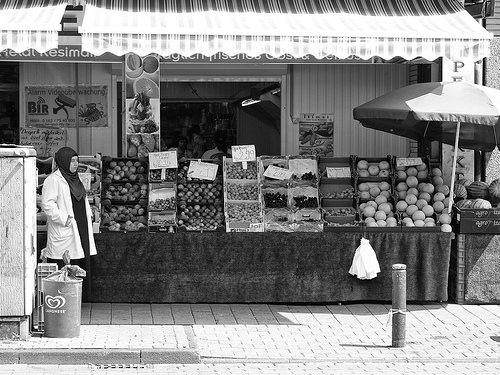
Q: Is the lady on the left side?
A: Yes, the lady is on the left of the image.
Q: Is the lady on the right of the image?
A: No, the lady is on the left of the image.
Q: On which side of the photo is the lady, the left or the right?
A: The lady is on the left of the image.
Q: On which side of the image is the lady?
A: The lady is on the left of the image.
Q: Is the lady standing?
A: Yes, the lady is standing.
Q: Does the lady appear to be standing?
A: Yes, the lady is standing.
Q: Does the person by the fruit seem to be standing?
A: Yes, the lady is standing.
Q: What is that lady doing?
A: The lady is standing.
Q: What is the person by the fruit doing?
A: The lady is standing.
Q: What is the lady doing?
A: The lady is standing.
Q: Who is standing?
A: The lady is standing.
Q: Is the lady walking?
A: No, the lady is standing.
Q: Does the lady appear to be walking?
A: No, the lady is standing.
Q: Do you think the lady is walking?
A: No, the lady is standing.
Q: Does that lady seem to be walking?
A: No, the lady is standing.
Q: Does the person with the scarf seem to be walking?
A: No, the lady is standing.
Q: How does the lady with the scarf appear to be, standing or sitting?
A: The lady is standing.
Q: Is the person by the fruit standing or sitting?
A: The lady is standing.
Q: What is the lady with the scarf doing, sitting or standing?
A: The lady is standing.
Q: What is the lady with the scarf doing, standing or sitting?
A: The lady is standing.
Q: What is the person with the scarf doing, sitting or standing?
A: The lady is standing.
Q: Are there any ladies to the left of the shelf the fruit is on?
A: Yes, there is a lady to the left of the shelf.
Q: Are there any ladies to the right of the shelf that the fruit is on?
A: No, the lady is to the left of the shelf.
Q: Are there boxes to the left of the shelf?
A: No, there is a lady to the left of the shelf.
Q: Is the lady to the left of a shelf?
A: Yes, the lady is to the left of a shelf.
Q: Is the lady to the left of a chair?
A: No, the lady is to the left of a shelf.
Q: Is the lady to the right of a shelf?
A: No, the lady is to the left of a shelf.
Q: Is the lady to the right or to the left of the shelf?
A: The lady is to the left of the shelf.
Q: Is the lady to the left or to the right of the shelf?
A: The lady is to the left of the shelf.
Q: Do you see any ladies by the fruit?
A: Yes, there is a lady by the fruit.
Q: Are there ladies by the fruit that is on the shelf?
A: Yes, there is a lady by the fruit.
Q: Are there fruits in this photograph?
A: Yes, there is a fruit.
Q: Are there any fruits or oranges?
A: Yes, there is a fruit.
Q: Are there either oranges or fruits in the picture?
A: Yes, there is a fruit.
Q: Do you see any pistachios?
A: No, there are no pistachios.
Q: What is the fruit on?
A: The fruit is on the shelf.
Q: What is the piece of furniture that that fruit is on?
A: The piece of furniture is a shelf.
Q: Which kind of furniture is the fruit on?
A: The fruit is on the shelf.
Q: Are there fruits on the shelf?
A: Yes, there is a fruit on the shelf.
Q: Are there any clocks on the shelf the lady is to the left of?
A: No, there is a fruit on the shelf.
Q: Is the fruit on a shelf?
A: Yes, the fruit is on a shelf.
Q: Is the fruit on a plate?
A: No, the fruit is on a shelf.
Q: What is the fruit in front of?
A: The fruit is in front of the window.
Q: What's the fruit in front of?
A: The fruit is in front of the window.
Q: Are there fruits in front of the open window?
A: Yes, there is a fruit in front of the window.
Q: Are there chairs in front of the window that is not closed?
A: No, there is a fruit in front of the window.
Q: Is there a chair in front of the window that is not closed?
A: No, there is a fruit in front of the window.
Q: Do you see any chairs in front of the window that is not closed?
A: No, there is a fruit in front of the window.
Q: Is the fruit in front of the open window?
A: Yes, the fruit is in front of the window.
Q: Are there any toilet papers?
A: No, there are no toilet papers.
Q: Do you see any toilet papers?
A: No, there are no toilet papers.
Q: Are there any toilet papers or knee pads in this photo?
A: No, there are no toilet papers or knee pads.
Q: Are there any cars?
A: No, there are no cars.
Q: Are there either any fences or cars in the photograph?
A: No, there are no cars or fences.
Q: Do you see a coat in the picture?
A: Yes, there is a coat.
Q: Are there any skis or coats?
A: Yes, there is a coat.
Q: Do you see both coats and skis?
A: No, there is a coat but no skis.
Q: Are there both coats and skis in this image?
A: No, there is a coat but no skis.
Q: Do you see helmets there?
A: No, there are no helmets.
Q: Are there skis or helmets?
A: No, there are no helmets or skis.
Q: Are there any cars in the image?
A: No, there are no cars.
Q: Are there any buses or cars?
A: No, there are no cars or buses.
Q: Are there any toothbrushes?
A: No, there are no toothbrushes.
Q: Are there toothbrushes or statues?
A: No, there are no toothbrushes or statues.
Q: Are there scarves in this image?
A: Yes, there is a scarf.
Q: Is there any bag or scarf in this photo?
A: Yes, there is a scarf.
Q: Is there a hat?
A: No, there are no hats.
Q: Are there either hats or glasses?
A: No, there are no hats or glasses.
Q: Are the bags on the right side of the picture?
A: Yes, the bags are on the right of the image.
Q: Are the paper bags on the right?
A: Yes, the bags are on the right of the image.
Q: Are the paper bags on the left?
A: No, the bags are on the right of the image.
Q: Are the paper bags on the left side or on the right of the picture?
A: The bags are on the right of the image.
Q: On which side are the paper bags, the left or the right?
A: The bags are on the right of the image.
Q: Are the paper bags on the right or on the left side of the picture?
A: The bags are on the right of the image.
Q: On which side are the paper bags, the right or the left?
A: The bags are on the right of the image.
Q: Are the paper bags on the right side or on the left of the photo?
A: The bags are on the right of the image.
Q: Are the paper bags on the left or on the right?
A: The bags are on the right of the image.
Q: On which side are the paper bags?
A: The bags are on the right of the image.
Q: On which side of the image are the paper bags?
A: The bags are on the right of the image.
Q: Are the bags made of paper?
A: Yes, the bags are made of paper.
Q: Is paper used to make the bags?
A: Yes, the bags are made of paper.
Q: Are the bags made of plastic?
A: No, the bags are made of paper.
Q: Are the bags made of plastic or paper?
A: The bags are made of paper.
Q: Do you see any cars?
A: No, there are no cars.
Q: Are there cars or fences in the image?
A: No, there are no cars or fences.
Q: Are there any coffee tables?
A: No, there are no coffee tables.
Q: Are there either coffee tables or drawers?
A: No, there are no coffee tables or drawers.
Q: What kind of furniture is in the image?
A: The furniture is a shelf.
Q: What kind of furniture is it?
A: The piece of furniture is a shelf.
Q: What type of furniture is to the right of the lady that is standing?
A: The piece of furniture is a shelf.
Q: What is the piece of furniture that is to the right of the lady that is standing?
A: The piece of furniture is a shelf.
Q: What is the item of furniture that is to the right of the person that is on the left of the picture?
A: The piece of furniture is a shelf.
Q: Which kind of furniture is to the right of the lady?
A: The piece of furniture is a shelf.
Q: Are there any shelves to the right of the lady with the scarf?
A: Yes, there is a shelf to the right of the lady.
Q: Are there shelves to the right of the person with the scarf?
A: Yes, there is a shelf to the right of the lady.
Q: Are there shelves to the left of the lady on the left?
A: No, the shelf is to the right of the lady.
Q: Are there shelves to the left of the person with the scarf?
A: No, the shelf is to the right of the lady.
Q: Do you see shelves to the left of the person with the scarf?
A: No, the shelf is to the right of the lady.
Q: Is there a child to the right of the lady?
A: No, there is a shelf to the right of the lady.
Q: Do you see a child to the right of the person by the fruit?
A: No, there is a shelf to the right of the lady.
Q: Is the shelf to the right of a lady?
A: Yes, the shelf is to the right of a lady.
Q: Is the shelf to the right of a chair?
A: No, the shelf is to the right of a lady.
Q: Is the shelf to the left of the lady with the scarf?
A: No, the shelf is to the right of the lady.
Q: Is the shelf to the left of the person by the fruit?
A: No, the shelf is to the right of the lady.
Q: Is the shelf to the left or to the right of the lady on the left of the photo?
A: The shelf is to the right of the lady.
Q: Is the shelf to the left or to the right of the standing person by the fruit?
A: The shelf is to the right of the lady.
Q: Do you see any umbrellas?
A: Yes, there is an umbrella.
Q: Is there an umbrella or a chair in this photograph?
A: Yes, there is an umbrella.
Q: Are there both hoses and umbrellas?
A: No, there is an umbrella but no hoses.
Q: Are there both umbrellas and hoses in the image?
A: No, there is an umbrella but no hoses.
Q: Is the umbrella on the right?
A: Yes, the umbrella is on the right of the image.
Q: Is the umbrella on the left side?
A: No, the umbrella is on the right of the image.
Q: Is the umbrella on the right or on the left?
A: The umbrella is on the right of the image.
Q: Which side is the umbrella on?
A: The umbrella is on the right of the image.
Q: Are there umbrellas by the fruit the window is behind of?
A: Yes, there is an umbrella by the fruit.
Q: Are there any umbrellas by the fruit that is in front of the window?
A: Yes, there is an umbrella by the fruit.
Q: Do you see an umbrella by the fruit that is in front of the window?
A: Yes, there is an umbrella by the fruit.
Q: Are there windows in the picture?
A: Yes, there is a window.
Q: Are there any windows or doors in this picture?
A: Yes, there is a window.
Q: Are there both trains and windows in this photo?
A: No, there is a window but no trains.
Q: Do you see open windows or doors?
A: Yes, there is an open window.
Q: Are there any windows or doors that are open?
A: Yes, the window is open.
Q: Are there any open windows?
A: Yes, there is an open window.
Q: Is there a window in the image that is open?
A: Yes, there is a window that is open.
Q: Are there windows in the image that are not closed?
A: Yes, there is a open window.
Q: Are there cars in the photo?
A: No, there are no cars.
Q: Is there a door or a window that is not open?
A: No, there is a window but it is open.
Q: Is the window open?
A: Yes, the window is open.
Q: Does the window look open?
A: Yes, the window is open.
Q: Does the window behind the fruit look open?
A: Yes, the window is open.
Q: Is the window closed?
A: No, the window is open.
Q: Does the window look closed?
A: No, the window is open.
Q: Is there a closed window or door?
A: No, there is a window but it is open.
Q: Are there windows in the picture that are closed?
A: No, there is a window but it is open.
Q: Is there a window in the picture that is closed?
A: No, there is a window but it is open.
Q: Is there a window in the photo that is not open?
A: No, there is a window but it is open.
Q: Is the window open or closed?
A: The window is open.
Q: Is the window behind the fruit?
A: Yes, the window is behind the fruit.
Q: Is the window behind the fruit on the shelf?
A: Yes, the window is behind the fruit.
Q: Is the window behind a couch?
A: No, the window is behind the fruit.